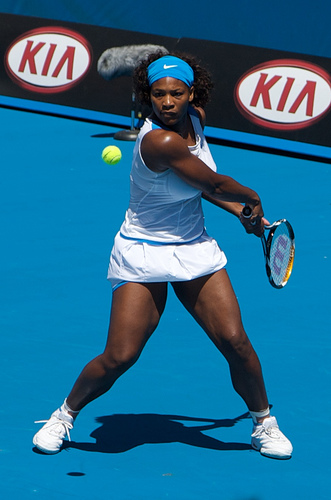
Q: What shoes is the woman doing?
A: Woman wearing white shoes.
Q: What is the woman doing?
A: Woman swinging a tennis racket.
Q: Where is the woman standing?
A: Women standing on blue court.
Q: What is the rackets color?
A: Black and yellow.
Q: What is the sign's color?
A: Black, red, and white sign.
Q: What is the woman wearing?
A: Women wearing a white dress.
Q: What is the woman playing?
A: The women is playing tennis.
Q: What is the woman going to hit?
A: A tennis ball.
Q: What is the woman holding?
A: A tennis racket.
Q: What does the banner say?
A: Kia.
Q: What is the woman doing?
A: Playing tennis.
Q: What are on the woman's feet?
A: Shoes.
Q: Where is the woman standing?
A: Tennis court.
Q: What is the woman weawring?
A: Tennis outfit.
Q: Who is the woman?
A: Serena Wiliams.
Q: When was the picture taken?
A: Daytime.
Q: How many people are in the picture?
A: One.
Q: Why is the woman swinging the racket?
A: To hit the ball.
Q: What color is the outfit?
A: White.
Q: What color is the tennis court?
A: Blue.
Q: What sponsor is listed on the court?
A: Kia.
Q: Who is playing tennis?
A: A woman.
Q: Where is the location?
A: Tennis court.